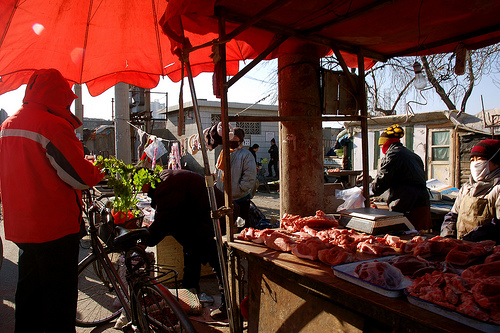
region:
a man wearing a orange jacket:
[11, 65, 103, 219]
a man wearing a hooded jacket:
[0, 48, 105, 249]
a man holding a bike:
[6, 100, 176, 275]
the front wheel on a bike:
[71, 222, 173, 320]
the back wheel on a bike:
[121, 266, 262, 328]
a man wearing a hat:
[371, 117, 436, 156]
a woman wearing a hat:
[462, 145, 498, 200]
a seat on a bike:
[106, 205, 182, 271]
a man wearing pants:
[9, 218, 159, 314]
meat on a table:
[225, 156, 492, 303]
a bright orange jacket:
[0, 68, 106, 245]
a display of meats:
[240, 206, 497, 320]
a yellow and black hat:
[371, 120, 409, 144]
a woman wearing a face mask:
[439, 137, 497, 252]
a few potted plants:
[93, 154, 164, 226]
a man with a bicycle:
[4, 57, 199, 329]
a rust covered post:
[268, 50, 333, 221]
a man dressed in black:
[134, 165, 241, 323]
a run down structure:
[339, 104, 489, 186]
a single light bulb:
[411, 58, 432, 93]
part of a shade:
[294, 302, 314, 324]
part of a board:
[280, 301, 291, 315]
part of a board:
[268, 275, 288, 298]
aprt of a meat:
[418, 263, 440, 305]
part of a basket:
[174, 256, 201, 293]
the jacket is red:
[0, 71, 90, 241]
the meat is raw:
[297, 229, 354, 263]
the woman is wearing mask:
[446, 134, 499, 239]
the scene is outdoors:
[2, 5, 489, 332]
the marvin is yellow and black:
[376, 115, 410, 146]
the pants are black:
[13, 250, 79, 331]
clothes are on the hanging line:
[141, 122, 240, 162]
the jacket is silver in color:
[218, 152, 256, 192]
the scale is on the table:
[338, 198, 415, 234]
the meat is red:
[241, 213, 498, 303]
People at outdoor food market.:
[8, 11, 489, 319]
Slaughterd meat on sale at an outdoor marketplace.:
[221, 179, 496, 331]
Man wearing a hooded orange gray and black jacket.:
[1, 56, 142, 247]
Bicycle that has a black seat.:
[70, 182, 209, 329]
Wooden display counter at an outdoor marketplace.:
[215, 239, 433, 329]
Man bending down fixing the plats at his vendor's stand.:
[110, 148, 253, 291]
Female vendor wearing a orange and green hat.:
[371, 110, 430, 210]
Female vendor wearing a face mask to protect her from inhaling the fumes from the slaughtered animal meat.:
[447, 133, 498, 216]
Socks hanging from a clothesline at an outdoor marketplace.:
[125, 115, 262, 152]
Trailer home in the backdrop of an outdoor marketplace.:
[351, 90, 481, 201]